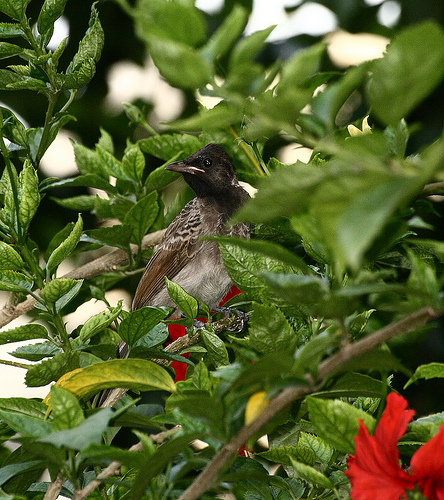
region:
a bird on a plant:
[108, 136, 276, 372]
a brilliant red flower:
[336, 387, 442, 495]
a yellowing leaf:
[40, 349, 183, 406]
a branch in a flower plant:
[180, 298, 440, 495]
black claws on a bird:
[217, 305, 252, 338]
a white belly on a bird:
[153, 263, 231, 313]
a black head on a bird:
[163, 137, 245, 195]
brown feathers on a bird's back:
[119, 200, 211, 308]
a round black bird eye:
[202, 156, 212, 168]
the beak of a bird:
[161, 158, 196, 175]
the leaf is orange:
[358, 438, 402, 488]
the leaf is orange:
[338, 459, 368, 484]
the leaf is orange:
[359, 447, 379, 477]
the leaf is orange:
[344, 421, 399, 493]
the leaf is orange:
[368, 447, 430, 493]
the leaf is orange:
[348, 419, 441, 455]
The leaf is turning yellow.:
[37, 359, 186, 421]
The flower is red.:
[333, 388, 443, 498]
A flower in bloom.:
[328, 380, 442, 498]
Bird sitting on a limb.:
[118, 137, 278, 374]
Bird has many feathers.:
[124, 133, 280, 381]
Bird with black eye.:
[110, 135, 301, 381]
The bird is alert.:
[75, 127, 294, 394]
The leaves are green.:
[1, 0, 441, 497]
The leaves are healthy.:
[1, 1, 443, 497]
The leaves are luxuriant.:
[0, 0, 442, 498]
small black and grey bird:
[90, 118, 284, 346]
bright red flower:
[331, 379, 438, 492]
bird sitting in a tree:
[23, 50, 282, 402]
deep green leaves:
[17, 93, 353, 430]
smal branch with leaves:
[186, 269, 427, 490]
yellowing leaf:
[26, 341, 194, 442]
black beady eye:
[178, 135, 222, 182]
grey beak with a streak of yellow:
[163, 152, 204, 190]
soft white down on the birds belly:
[161, 234, 250, 320]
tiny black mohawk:
[195, 122, 246, 164]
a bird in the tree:
[79, 95, 302, 374]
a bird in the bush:
[64, 133, 313, 343]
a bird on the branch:
[90, 133, 335, 381]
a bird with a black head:
[62, 129, 396, 399]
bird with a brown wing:
[61, 138, 314, 380]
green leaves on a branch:
[36, 204, 398, 453]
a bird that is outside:
[67, 135, 358, 417]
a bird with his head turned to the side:
[91, 139, 333, 370]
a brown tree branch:
[207, 278, 383, 498]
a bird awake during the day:
[55, 130, 346, 365]